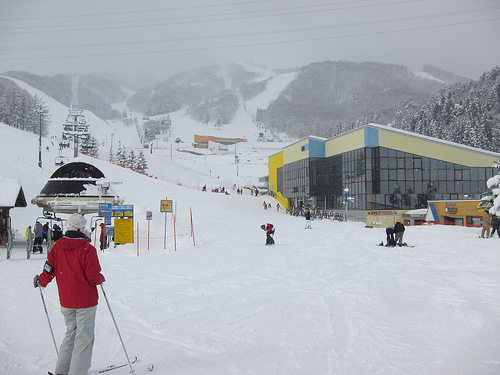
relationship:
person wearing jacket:
[34, 212, 102, 375] [38, 238, 105, 309]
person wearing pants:
[34, 212, 102, 375] [54, 300, 102, 374]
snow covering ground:
[287, 242, 349, 301] [135, 283, 474, 365]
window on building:
[273, 146, 496, 215] [268, 120, 498, 227]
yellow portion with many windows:
[264, 154, 294, 204] [264, 150, 481, 206]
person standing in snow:
[477, 205, 497, 240] [232, 226, 498, 373]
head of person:
[61, 210, 90, 234] [29, 212, 106, 372]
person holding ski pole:
[34, 212, 102, 375] [96, 272, 138, 373]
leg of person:
[55, 306, 72, 373] [28, 211, 121, 373]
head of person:
[391, 212, 403, 226] [20, 212, 142, 373]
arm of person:
[35, 238, 60, 293] [24, 207, 105, 374]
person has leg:
[479, 207, 492, 237] [479, 221, 487, 236]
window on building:
[371, 154, 378, 162] [268, 120, 498, 227]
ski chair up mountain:
[52, 90, 97, 165] [1, 63, 161, 130]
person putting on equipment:
[392, 220, 406, 246] [375, 240, 417, 248]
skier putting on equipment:
[386, 225, 394, 240] [375, 240, 417, 248]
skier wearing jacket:
[302, 206, 312, 228] [302, 210, 312, 220]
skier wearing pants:
[302, 206, 312, 228] [304, 218, 310, 226]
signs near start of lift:
[91, 199, 149, 254] [45, 95, 116, 261]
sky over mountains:
[1, 0, 499, 90] [12, 21, 489, 156]